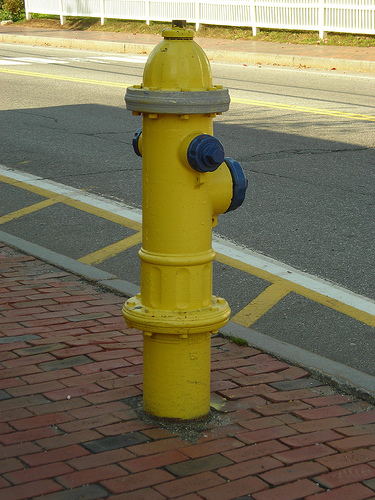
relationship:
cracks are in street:
[250, 140, 363, 191] [1, 42, 374, 373]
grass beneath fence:
[73, 18, 374, 49] [18, 1, 373, 42]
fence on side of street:
[18, 1, 373, 42] [1, 42, 374, 373]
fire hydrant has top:
[123, 15, 242, 422] [123, 14, 231, 114]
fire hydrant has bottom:
[123, 15, 242, 422] [124, 288, 232, 422]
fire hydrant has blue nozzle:
[123, 15, 242, 422] [224, 158, 248, 209]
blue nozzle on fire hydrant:
[192, 138, 223, 167] [123, 15, 242, 422]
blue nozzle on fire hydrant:
[224, 158, 248, 209] [123, 15, 242, 422]